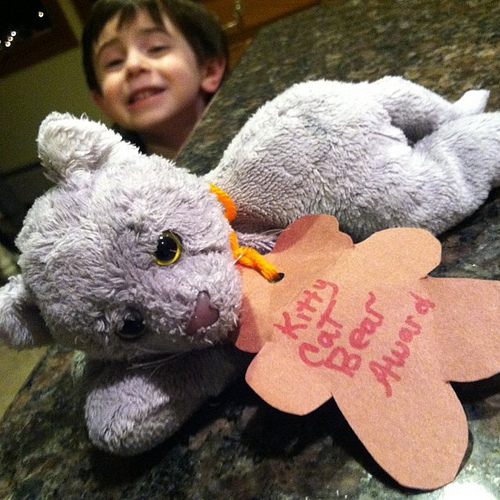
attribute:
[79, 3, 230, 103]
hair — straight, brown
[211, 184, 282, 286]
yarn — yellow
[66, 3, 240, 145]
boy — young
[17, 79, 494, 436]
bear — paper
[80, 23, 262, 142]
boy — smile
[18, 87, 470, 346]
animal — white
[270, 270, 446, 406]
letters — red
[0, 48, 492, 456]
animal — stuffed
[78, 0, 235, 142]
child — small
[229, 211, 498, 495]
tag — brown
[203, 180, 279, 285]
string — yellow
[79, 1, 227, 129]
boy — little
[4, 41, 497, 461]
cat — kitty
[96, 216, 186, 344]
eyes — green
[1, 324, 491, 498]
counter top — grey marble